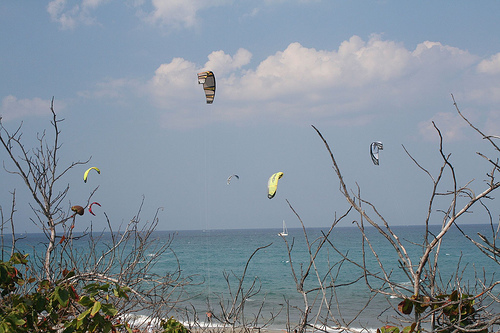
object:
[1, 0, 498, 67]
sky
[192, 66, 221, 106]
kites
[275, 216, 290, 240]
boat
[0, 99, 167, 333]
trees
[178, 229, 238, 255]
water